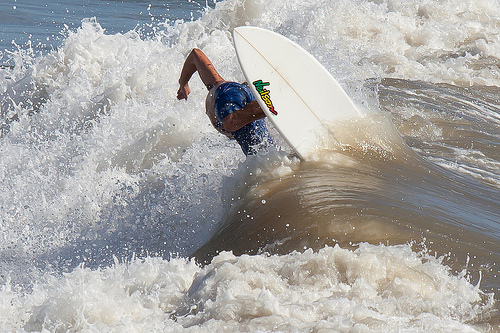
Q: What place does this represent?
A: It represents the ocean.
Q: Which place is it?
A: It is an ocean.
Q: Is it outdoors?
A: Yes, it is outdoors.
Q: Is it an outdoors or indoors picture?
A: It is outdoors.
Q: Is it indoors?
A: No, it is outdoors.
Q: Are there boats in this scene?
A: No, there are no boats.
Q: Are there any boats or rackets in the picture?
A: No, there are no boats or rackets.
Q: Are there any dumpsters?
A: No, there are no dumpsters.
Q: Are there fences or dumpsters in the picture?
A: No, there are no dumpsters or fences.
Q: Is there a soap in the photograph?
A: No, there are no soaps.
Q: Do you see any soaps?
A: No, there are no soaps.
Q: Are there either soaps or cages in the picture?
A: No, there are no soaps or cages.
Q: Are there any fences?
A: No, there are no fences.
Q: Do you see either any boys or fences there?
A: No, there are no fences or boys.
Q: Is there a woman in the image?
A: No, there are no women.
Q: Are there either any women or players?
A: No, there are no women or players.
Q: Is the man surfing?
A: Yes, the man is surfing.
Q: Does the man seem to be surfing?
A: Yes, the man is surfing.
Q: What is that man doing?
A: The man is surfing.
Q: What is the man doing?
A: The man is surfing.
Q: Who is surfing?
A: The man is surfing.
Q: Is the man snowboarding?
A: No, the man is surfing.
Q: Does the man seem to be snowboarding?
A: No, the man is surfing.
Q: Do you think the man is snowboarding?
A: No, the man is surfing.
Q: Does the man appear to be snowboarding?
A: No, the man is surfing.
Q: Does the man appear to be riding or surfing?
A: The man is surfing.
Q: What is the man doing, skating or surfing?
A: The man is surfing.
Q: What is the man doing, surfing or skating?
A: The man is surfing.